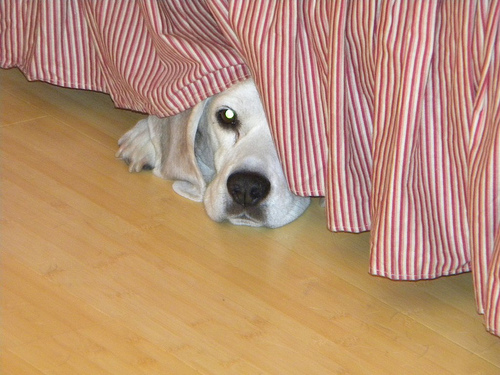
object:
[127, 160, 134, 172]
toenail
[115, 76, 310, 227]
dog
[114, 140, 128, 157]
toenail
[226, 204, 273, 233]
mouth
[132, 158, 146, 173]
nails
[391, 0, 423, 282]
candy stripe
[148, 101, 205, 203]
ear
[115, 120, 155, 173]
claws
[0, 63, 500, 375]
floor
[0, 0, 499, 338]
bed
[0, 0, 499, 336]
bed skirt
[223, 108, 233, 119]
reflection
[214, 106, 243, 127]
eye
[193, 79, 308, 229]
head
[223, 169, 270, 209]
nose